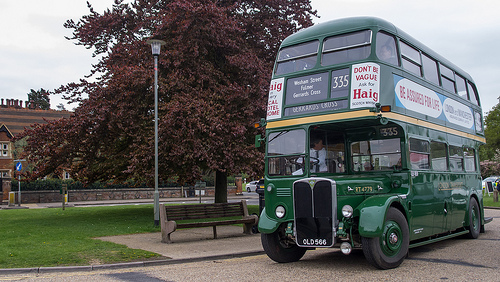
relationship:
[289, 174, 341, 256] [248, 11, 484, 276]
grill on bus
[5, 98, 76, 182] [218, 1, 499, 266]
building near bus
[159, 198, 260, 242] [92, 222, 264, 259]
bench on sidewalk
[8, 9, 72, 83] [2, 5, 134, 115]
cloud in sky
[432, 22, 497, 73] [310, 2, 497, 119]
cloud in sky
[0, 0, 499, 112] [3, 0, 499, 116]
clouds in sky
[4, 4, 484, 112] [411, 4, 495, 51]
clouds in sky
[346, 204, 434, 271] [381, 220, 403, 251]
tire with hub cap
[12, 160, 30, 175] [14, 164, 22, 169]
flag with arrow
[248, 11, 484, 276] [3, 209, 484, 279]
bus on street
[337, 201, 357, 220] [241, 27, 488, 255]
light on bus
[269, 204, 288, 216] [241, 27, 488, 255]
light on bus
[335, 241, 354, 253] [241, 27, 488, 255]
light on bus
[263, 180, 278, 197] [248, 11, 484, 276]
light on bus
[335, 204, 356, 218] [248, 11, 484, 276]
light on bus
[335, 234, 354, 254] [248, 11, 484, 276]
light on bus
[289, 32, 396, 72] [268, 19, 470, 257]
windows on bus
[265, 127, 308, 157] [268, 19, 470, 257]
windows on bus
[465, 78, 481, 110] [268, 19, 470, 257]
windows on bus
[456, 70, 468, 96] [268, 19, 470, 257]
windows on bus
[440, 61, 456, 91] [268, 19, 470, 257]
windows on bus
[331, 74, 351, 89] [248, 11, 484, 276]
number on bus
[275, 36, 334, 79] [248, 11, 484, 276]
windows on bus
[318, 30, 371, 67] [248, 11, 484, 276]
windows on bus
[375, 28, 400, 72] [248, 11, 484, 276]
windows on bus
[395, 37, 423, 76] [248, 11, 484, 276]
windows on bus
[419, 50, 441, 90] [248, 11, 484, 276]
windows on bus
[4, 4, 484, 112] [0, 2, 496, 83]
clouds in sky